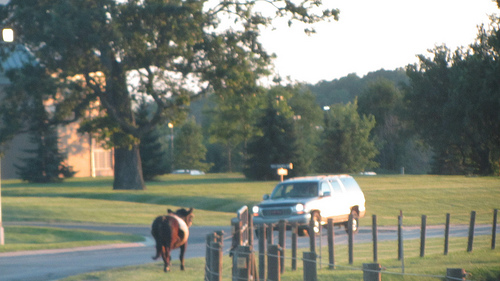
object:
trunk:
[103, 69, 144, 190]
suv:
[250, 174, 366, 239]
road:
[86, 249, 126, 266]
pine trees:
[11, 71, 402, 183]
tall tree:
[0, 0, 279, 191]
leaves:
[149, 47, 174, 59]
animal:
[150, 207, 195, 273]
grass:
[88, 250, 500, 279]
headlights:
[252, 206, 259, 213]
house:
[1, 66, 118, 180]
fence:
[202, 204, 497, 280]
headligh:
[295, 203, 304, 211]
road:
[0, 247, 104, 281]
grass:
[0, 174, 490, 253]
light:
[2, 27, 15, 43]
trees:
[405, 15, 499, 178]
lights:
[252, 203, 304, 216]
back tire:
[345, 207, 360, 235]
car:
[252, 174, 367, 237]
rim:
[352, 218, 358, 230]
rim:
[315, 218, 320, 233]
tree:
[241, 85, 316, 181]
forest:
[151, 0, 498, 182]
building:
[3, 50, 119, 181]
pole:
[206, 214, 500, 281]